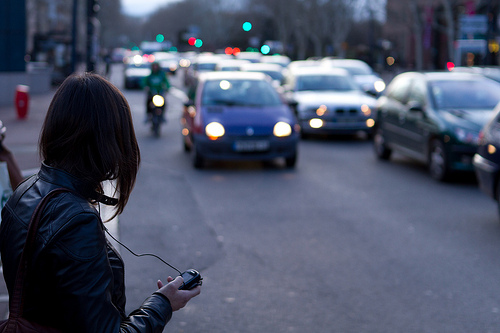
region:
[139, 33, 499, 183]
Vehicle motion makes blurry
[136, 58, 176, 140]
Lone motorcyclist rides street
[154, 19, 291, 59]
Traffic lights Christmas colors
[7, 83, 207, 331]
Girl foreground not blurry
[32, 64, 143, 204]
Long dark hair hides face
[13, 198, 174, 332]
Familiar black leather jacket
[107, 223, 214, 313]
Ear wire hear music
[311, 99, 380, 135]
Car grill extra running lights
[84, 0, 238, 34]
Trees encompassed blurry fog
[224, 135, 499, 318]
No traffic lane markings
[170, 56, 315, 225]
car is red and blue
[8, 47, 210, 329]
woman in black leather jacket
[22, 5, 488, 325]
a city landscape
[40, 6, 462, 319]
a busy street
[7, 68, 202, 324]
a woman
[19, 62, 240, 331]
a woman watching traffic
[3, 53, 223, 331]
the woman holds a black object in her hand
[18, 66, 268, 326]
there is a cord attached to the object in the woman's hand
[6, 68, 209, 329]
the woman is wearing a leather jacket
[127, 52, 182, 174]
a motorcyle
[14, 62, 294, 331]
a woman stands at the side of a busy street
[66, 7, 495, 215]
traffic is very heavy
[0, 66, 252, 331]
Person wearing black jacket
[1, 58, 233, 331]
Person holding a phone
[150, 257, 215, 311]
Black phone in a person's hand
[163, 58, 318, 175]
Car driving on the street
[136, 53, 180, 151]
Person on a motorcycle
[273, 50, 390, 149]
Car driving in traffic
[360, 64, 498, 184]
Car driving in traffic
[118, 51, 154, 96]
Car driving in traffic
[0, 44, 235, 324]
Person with black hair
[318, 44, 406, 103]
Car driving in traffic